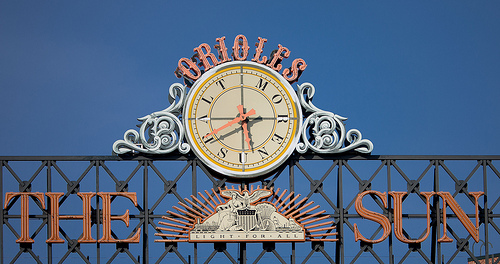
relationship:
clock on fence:
[173, 56, 308, 183] [5, 147, 499, 263]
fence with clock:
[5, 147, 499, 263] [173, 56, 308, 183]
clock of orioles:
[173, 56, 308, 183] [170, 27, 310, 84]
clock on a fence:
[173, 56, 308, 183] [5, 147, 499, 263]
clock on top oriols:
[173, 56, 308, 183] [170, 27, 310, 84]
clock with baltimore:
[173, 56, 308, 183] [195, 74, 292, 165]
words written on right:
[346, 188, 487, 246] [474, 4, 498, 256]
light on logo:
[3, 1, 499, 264] [151, 179, 349, 247]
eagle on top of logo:
[219, 187, 274, 206] [151, 179, 349, 247]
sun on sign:
[151, 179, 349, 247] [186, 187, 310, 245]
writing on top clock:
[170, 27, 310, 84] [173, 56, 308, 183]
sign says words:
[2, 183, 487, 248] [346, 188, 487, 246]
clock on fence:
[173, 56, 308, 183] [6, 151, 483, 257]